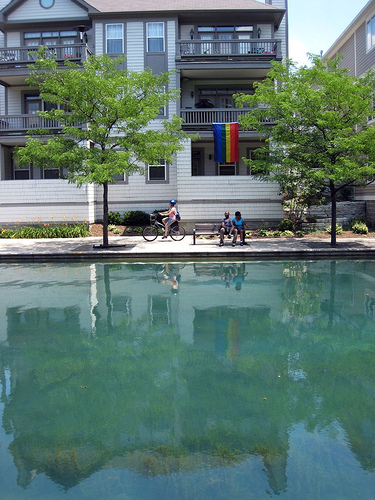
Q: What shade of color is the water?
A: Blue.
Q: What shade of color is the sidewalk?
A: Gray.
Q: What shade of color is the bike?
A: Black.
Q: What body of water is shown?
A: A pool.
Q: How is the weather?
A: Clear.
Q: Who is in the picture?
A: A man, woman and boy.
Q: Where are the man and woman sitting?
A: A bench.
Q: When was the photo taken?
A: Daytime.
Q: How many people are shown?
A: Three.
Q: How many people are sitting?
A: Two.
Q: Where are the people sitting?
A: Bench.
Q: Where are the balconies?
A: Building.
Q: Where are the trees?
A: Sidewalk.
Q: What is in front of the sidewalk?
A: Water.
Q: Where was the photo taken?
A: By a pool.